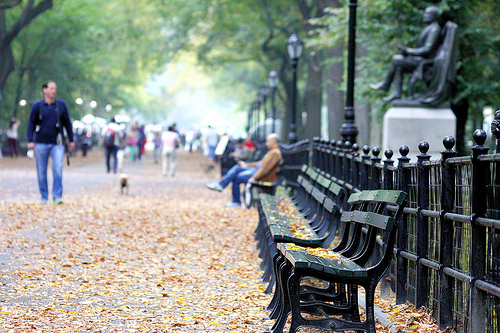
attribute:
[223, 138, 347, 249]
bench — blurry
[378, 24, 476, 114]
statue — shadow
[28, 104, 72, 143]
sweater — blue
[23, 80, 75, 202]
man — walking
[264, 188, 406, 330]
bench — line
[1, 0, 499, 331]
leaves — brown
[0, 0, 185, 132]
trees — lots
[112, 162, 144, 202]
dog — walking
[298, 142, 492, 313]
fencing — black, iron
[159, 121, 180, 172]
people — several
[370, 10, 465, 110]
statue — black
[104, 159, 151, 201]
dog — photo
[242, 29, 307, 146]
lamp posts — black